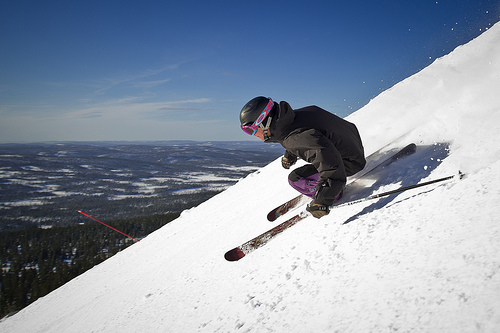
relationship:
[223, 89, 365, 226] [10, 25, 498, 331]
skier on snow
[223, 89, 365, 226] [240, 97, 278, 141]
skier wears goggles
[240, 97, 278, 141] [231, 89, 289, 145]
goggles on head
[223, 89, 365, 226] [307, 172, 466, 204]
skier carries pole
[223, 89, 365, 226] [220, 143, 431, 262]
skier on skis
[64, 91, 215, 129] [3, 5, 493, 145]
clouds in sky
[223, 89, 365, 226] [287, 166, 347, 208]
skier wears pants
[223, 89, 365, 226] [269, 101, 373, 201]
skier wears jacket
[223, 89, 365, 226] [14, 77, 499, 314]
skier on hill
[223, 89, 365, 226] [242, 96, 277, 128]
skier wears hat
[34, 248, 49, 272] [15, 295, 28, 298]
tree at bottom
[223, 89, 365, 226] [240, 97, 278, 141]
skier has goggles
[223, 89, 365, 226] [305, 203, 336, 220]
skier has glove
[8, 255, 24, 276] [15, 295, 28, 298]
tree at bottom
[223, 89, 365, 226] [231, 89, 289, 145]
skier has head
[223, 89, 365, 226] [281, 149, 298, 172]
skier has hand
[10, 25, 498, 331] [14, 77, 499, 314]
snow on hill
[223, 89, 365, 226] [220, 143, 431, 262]
skier wears skis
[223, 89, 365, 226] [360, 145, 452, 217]
skier casts shadow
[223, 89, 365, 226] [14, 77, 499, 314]
skier going down hill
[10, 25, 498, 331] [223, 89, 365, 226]
snow near skier